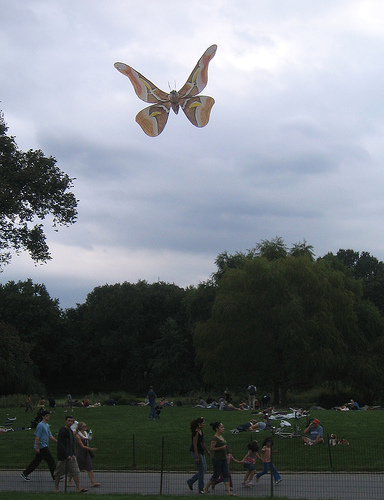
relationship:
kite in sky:
[113, 42, 216, 137] [217, 1, 383, 238]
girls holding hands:
[227, 440, 283, 489] [235, 455, 247, 467]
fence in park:
[96, 439, 190, 500] [0, 2, 383, 499]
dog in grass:
[326, 433, 351, 448] [351, 412, 383, 472]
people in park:
[246, 381, 259, 413] [0, 2, 383, 499]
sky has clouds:
[217, 1, 383, 238] [82, 147, 339, 234]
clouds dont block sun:
[217, 1, 383, 238] [218, 2, 383, 108]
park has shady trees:
[0, 2, 383, 499] [192, 256, 383, 407]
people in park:
[230, 414, 269, 435] [0, 2, 383, 499]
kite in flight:
[113, 42, 216, 137] [4, 1, 383, 249]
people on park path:
[201, 420, 237, 500] [278, 471, 383, 500]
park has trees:
[0, 2, 383, 499] [0, 241, 383, 397]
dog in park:
[326, 433, 351, 448] [0, 2, 383, 499]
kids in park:
[240, 441, 259, 488] [0, 2, 383, 499]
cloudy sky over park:
[217, 1, 383, 238] [0, 2, 383, 499]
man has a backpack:
[246, 381, 259, 413] [250, 386, 255, 395]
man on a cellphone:
[301, 419, 324, 446] [308, 420, 315, 429]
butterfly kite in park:
[113, 42, 216, 137] [0, 2, 383, 499]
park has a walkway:
[0, 2, 383, 499] [0, 471, 381, 500]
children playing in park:
[223, 438, 281, 494] [0, 2, 383, 499]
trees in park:
[0, 241, 383, 397] [0, 2, 383, 499]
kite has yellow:
[113, 42, 216, 137] [188, 102, 200, 110]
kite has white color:
[113, 42, 216, 137] [143, 109, 158, 135]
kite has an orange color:
[113, 42, 216, 137] [124, 69, 143, 96]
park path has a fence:
[0, 471, 381, 500] [277, 435, 383, 499]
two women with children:
[187, 418, 210, 496] [223, 438, 281, 494]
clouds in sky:
[78, 138, 383, 246] [217, 1, 383, 238]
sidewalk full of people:
[0, 471, 381, 500] [201, 420, 237, 500]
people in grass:
[230, 414, 269, 435] [351, 412, 383, 472]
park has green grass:
[0, 2, 383, 499] [96, 414, 190, 470]